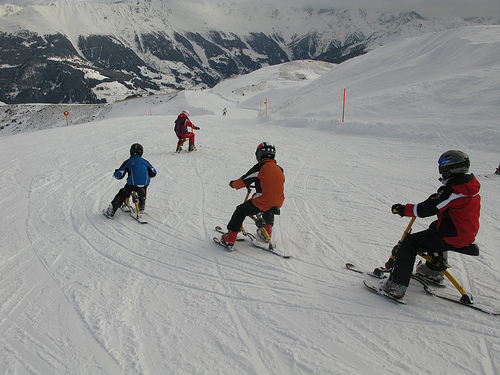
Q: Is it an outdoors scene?
A: Yes, it is outdoors.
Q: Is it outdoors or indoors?
A: It is outdoors.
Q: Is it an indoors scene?
A: No, it is outdoors.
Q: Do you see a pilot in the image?
A: No, there are no pilots.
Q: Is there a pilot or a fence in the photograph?
A: No, there are no pilots or fences.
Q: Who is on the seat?
A: The boy is on the seat.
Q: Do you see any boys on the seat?
A: Yes, there is a boy on the seat.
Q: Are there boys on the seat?
A: Yes, there is a boy on the seat.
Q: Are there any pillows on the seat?
A: No, there is a boy on the seat.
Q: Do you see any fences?
A: No, there are no fences.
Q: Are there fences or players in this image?
A: No, there are no fences or players.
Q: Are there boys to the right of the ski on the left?
A: Yes, there is a boy to the right of the ski.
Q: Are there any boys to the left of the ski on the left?
A: No, the boy is to the right of the ski.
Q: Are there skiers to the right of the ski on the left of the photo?
A: No, there is a boy to the right of the ski.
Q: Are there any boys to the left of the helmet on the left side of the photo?
A: No, the boy is to the right of the helmet.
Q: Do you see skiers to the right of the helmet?
A: No, there is a boy to the right of the helmet.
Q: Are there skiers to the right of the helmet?
A: No, there is a boy to the right of the helmet.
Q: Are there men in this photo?
A: No, there are no men.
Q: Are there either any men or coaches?
A: No, there are no men or coaches.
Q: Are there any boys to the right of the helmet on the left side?
A: Yes, there is a boy to the right of the helmet.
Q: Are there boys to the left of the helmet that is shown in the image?
A: No, the boy is to the right of the helmet.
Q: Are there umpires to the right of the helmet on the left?
A: No, there is a boy to the right of the helmet.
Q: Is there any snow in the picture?
A: Yes, there is snow.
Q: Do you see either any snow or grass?
A: Yes, there is snow.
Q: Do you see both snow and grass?
A: No, there is snow but no grass.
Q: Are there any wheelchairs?
A: No, there are no wheelchairs.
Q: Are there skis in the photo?
A: Yes, there are skis.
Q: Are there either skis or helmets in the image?
A: Yes, there are skis.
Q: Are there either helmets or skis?
A: Yes, there are skis.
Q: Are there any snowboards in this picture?
A: No, there are no snowboards.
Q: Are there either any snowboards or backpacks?
A: No, there are no snowboards or backpacks.